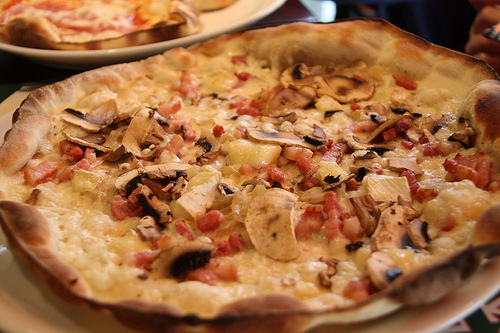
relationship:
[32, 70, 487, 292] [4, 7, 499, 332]
pizza on top of plate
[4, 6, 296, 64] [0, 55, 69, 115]
plate on top of table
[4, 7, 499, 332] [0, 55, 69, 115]
plate on table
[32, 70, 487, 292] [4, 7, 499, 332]
pizza covering plate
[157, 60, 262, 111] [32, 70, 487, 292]
cheese on top of food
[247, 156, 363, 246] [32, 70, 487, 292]
tomatoes on top of pizza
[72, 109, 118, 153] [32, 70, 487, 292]
mushrooms on top of pizza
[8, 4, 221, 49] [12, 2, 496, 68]
pizza in background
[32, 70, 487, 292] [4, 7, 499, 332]
pizza on plate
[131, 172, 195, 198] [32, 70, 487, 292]
meat on top of pizza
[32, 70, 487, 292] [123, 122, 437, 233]
pizza has toppings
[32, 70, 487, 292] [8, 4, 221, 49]
pizza behind pizza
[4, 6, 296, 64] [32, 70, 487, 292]
plate behind pizza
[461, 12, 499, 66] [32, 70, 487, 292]
hand right of pizza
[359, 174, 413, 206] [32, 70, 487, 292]
chicken on pizza